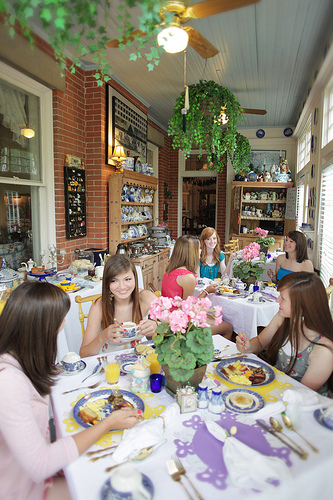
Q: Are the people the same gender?
A: Yes, all the people are female.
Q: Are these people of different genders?
A: No, all the people are female.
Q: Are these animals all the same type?
A: Yes, all the animals are bugs.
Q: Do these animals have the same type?
A: Yes, all the animals are bugs.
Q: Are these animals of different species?
A: No, all the animals are bugs.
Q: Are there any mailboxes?
A: No, there are no mailboxes.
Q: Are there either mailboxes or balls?
A: No, there are no mailboxes or balls.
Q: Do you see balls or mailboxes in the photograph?
A: No, there are no mailboxes or balls.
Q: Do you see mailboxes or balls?
A: No, there are no mailboxes or balls.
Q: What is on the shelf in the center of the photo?
A: The dishes are on the shelf.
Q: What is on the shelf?
A: The dishes are on the shelf.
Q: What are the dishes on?
A: The dishes are on the shelf.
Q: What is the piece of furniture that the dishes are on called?
A: The piece of furniture is a shelf.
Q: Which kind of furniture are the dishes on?
A: The dishes are on the shelf.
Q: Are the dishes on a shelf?
A: Yes, the dishes are on a shelf.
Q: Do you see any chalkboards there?
A: No, there are no chalkboards.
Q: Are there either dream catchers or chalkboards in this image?
A: No, there are no chalkboards or dream catchers.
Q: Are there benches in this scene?
A: No, there are no benches.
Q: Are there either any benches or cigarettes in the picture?
A: No, there are no benches or cigarettes.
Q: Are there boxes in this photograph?
A: No, there are no boxes.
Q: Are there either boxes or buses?
A: No, there are no boxes or buses.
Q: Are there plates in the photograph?
A: Yes, there is a plate.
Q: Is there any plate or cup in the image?
A: Yes, there is a plate.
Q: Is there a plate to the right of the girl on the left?
A: Yes, there is a plate to the right of the girl.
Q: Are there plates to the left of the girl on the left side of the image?
A: No, the plate is to the right of the girl.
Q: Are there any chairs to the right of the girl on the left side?
A: No, there is a plate to the right of the girl.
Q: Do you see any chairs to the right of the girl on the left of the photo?
A: No, there is a plate to the right of the girl.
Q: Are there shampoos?
A: No, there are no shampoos.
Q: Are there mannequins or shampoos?
A: No, there are no shampoos or mannequins.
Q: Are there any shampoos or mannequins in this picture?
A: No, there are no shampoos or mannequins.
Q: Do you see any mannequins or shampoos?
A: No, there are no shampoos or mannequins.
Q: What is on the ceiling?
A: The fans are on the ceiling.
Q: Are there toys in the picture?
A: No, there are no toys.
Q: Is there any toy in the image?
A: No, there are no toys.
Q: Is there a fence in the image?
A: No, there are no fences.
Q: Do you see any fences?
A: No, there are no fences.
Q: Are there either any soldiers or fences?
A: No, there are no fences or soldiers.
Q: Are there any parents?
A: No, there are no parents.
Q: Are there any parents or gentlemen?
A: No, there are no parents or gentlemen.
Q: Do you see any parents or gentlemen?
A: No, there are no parents or gentlemen.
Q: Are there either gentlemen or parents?
A: No, there are no parents or gentlemen.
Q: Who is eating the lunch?
A: The girls are eating the lunch.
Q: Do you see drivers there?
A: No, there are no drivers.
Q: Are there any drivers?
A: No, there are no drivers.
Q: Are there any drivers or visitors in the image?
A: No, there are no drivers or visitors.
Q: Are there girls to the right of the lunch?
A: Yes, there is a girl to the right of the lunch.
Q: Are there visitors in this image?
A: No, there are no visitors.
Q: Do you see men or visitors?
A: No, there are no visitors or men.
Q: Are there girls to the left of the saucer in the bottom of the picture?
A: Yes, there is a girl to the left of the saucer.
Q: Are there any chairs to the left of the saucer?
A: No, there is a girl to the left of the saucer.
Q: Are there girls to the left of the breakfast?
A: Yes, there is a girl to the left of the breakfast.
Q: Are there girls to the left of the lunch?
A: Yes, there is a girl to the left of the lunch.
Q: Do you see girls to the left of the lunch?
A: Yes, there is a girl to the left of the lunch.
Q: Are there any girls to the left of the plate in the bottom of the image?
A: Yes, there is a girl to the left of the plate.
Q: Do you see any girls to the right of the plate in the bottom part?
A: No, the girl is to the left of the plate.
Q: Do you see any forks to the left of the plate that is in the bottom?
A: No, there is a girl to the left of the plate.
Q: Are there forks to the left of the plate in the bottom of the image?
A: No, there is a girl to the left of the plate.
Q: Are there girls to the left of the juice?
A: Yes, there is a girl to the left of the juice.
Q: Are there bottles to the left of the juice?
A: No, there is a girl to the left of the juice.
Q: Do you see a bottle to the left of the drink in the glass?
A: No, there is a girl to the left of the juice.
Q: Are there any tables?
A: Yes, there is a table.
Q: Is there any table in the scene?
A: Yes, there is a table.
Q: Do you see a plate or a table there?
A: Yes, there is a table.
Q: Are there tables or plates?
A: Yes, there is a table.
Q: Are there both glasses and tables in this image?
A: Yes, there are both a table and glasses.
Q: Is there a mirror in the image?
A: No, there are no mirrors.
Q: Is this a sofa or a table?
A: This is a table.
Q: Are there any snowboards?
A: No, there are no snowboards.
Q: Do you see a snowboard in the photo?
A: No, there are no snowboards.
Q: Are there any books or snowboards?
A: No, there are no snowboards or books.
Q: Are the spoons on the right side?
A: Yes, the spoons are on the right of the image.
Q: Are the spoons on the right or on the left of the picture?
A: The spoons are on the right of the image.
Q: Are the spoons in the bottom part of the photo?
A: Yes, the spoons are in the bottom of the image.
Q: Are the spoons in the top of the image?
A: No, the spoons are in the bottom of the image.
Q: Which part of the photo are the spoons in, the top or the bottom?
A: The spoons are in the bottom of the image.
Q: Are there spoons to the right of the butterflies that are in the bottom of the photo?
A: Yes, there are spoons to the right of the butterflies.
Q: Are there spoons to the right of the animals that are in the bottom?
A: Yes, there are spoons to the right of the butterflies.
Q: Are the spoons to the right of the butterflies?
A: Yes, the spoons are to the right of the butterflies.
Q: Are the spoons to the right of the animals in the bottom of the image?
A: Yes, the spoons are to the right of the butterflies.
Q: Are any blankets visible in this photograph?
A: No, there are no blankets.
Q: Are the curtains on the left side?
A: Yes, the curtains are on the left of the image.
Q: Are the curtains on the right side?
A: No, the curtains are on the left of the image.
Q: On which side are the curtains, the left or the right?
A: The curtains are on the left of the image.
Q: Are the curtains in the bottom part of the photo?
A: No, the curtains are in the top of the image.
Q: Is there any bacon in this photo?
A: No, there is no bacon.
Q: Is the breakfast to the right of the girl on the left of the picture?
A: Yes, the breakfast is to the right of the girl.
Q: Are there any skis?
A: No, there are no skis.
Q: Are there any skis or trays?
A: No, there are no skis or trays.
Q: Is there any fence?
A: No, there are no fences.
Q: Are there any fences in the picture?
A: No, there are no fences.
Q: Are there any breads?
A: No, there are no breads.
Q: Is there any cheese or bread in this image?
A: No, there are no breads or cheese.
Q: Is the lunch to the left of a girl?
A: Yes, the lunch is to the left of a girl.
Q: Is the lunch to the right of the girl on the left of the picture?
A: Yes, the lunch is to the right of the girl.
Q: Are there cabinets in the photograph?
A: Yes, there is a cabinet.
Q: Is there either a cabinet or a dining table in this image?
A: Yes, there is a cabinet.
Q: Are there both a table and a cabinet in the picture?
A: Yes, there are both a cabinet and a table.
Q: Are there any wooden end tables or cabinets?
A: Yes, there is a wood cabinet.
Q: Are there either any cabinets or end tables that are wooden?
A: Yes, the cabinet is wooden.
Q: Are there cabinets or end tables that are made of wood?
A: Yes, the cabinet is made of wood.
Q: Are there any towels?
A: No, there are no towels.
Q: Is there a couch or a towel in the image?
A: No, there are no towels or couches.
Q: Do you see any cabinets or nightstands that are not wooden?
A: No, there is a cabinet but it is wooden.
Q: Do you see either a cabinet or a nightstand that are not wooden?
A: No, there is a cabinet but it is wooden.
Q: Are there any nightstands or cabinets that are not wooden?
A: No, there is a cabinet but it is wooden.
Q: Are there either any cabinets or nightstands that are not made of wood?
A: No, there is a cabinet but it is made of wood.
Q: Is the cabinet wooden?
A: Yes, the cabinet is wooden.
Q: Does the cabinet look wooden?
A: Yes, the cabinet is wooden.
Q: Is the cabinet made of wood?
A: Yes, the cabinet is made of wood.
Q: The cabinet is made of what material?
A: The cabinet is made of wood.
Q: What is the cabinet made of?
A: The cabinet is made of wood.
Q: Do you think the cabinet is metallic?
A: No, the cabinet is wooden.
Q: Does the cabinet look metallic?
A: No, the cabinet is wooden.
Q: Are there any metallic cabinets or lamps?
A: No, there is a cabinet but it is wooden.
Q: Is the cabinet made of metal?
A: No, the cabinet is made of wood.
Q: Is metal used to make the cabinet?
A: No, the cabinet is made of wood.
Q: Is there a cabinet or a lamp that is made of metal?
A: No, there is a cabinet but it is made of wood.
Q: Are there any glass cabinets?
A: No, there is a cabinet but it is made of wood.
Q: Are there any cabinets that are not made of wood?
A: No, there is a cabinet but it is made of wood.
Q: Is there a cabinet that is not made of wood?
A: No, there is a cabinet but it is made of wood.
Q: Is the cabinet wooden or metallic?
A: The cabinet is wooden.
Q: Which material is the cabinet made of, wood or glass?
A: The cabinet is made of wood.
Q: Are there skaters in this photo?
A: No, there are no skaters.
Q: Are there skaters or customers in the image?
A: No, there are no skaters or customers.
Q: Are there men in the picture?
A: No, there are no men.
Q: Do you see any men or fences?
A: No, there are no men or fences.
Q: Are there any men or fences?
A: No, there are no men or fences.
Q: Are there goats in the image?
A: No, there are no goats.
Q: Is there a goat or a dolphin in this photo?
A: No, there are no goats or dolphins.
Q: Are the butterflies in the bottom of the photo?
A: Yes, the butterflies are in the bottom of the image.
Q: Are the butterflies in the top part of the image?
A: No, the butterflies are in the bottom of the image.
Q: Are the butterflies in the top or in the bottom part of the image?
A: The butterflies are in the bottom of the image.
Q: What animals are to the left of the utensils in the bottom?
A: The animals are butterflies.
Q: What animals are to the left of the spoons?
A: The animals are butterflies.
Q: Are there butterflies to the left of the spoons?
A: Yes, there are butterflies to the left of the spoons.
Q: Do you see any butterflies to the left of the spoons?
A: Yes, there are butterflies to the left of the spoons.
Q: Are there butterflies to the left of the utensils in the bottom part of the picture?
A: Yes, there are butterflies to the left of the spoons.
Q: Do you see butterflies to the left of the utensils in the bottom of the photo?
A: Yes, there are butterflies to the left of the spoons.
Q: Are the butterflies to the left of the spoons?
A: Yes, the butterflies are to the left of the spoons.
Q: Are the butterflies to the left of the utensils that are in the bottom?
A: Yes, the butterflies are to the left of the spoons.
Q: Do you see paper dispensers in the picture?
A: No, there are no paper dispensers.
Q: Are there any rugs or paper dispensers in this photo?
A: No, there are no paper dispensers or rugs.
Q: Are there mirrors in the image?
A: No, there are no mirrors.